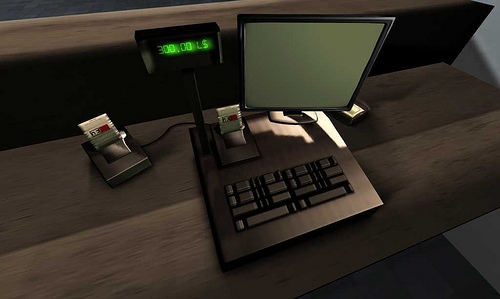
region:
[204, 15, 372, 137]
the monitor is black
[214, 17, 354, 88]
the monitor is black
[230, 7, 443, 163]
the monitor is black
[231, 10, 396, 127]
A black computer monitor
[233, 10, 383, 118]
The screen is grey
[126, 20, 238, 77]
Green lettering on the register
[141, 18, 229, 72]
The lettering is glowing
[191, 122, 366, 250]
The buttons are black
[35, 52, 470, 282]
The counter is brown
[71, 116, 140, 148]
White and red papers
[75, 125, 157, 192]
A shiny silver metal base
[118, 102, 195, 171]
A short black cord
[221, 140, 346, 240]
The buttons are different sizes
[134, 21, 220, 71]
price screen on a register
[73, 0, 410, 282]
an electronic money register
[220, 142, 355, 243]
a black keyboard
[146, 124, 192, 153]
a black cord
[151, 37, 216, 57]
numbers on a machine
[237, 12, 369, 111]
screen on the cash register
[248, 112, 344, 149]
light hitting the keyboard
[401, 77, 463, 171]
wooden desk under the machine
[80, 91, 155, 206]
a square electronic box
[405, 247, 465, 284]
dark gray flooring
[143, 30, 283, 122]
Green writing on register.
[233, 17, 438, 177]
Black and gray monitor.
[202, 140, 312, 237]
Black keyboard on machine.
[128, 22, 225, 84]
Machine says 300,00 l.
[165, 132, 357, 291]
Keyboard on dark surface.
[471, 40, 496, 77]
Wall is gray in color.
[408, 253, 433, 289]
Floor is dark gray in color.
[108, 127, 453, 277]
Machine is sitting on dark counter top.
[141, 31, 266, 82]
Small screen connected to black pole.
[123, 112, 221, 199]
Black wire connecting machine.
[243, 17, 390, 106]
a flat computer screen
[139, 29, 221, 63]
timer display connected to the computer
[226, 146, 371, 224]
keys of the computer connected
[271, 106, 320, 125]
a stand to hold the computer screen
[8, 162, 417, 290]
a wooden table which holds the computer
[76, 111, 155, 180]
a small box to hold the calendar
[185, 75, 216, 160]
a thin stand to hold the timer display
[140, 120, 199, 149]
a wire connection from the computer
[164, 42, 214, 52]
glass used to display timer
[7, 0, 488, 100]
a wood wall for the safety of computer